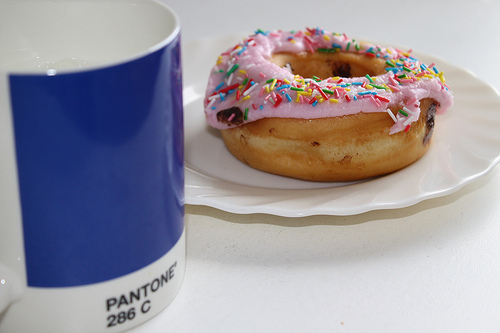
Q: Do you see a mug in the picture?
A: Yes, there is a mug.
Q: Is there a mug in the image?
A: Yes, there is a mug.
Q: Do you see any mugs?
A: Yes, there is a mug.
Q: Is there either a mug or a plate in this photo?
A: Yes, there is a mug.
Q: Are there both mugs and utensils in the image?
A: No, there is a mug but no utensils.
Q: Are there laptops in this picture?
A: No, there are no laptops.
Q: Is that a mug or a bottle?
A: That is a mug.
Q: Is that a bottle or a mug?
A: That is a mug.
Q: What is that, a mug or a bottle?
A: That is a mug.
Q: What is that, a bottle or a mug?
A: That is a mug.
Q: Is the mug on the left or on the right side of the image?
A: The mug is on the left of the image.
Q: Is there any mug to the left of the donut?
A: Yes, there is a mug to the left of the donut.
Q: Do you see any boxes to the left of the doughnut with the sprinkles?
A: No, there is a mug to the left of the donut.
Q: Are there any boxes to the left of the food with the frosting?
A: No, there is a mug to the left of the donut.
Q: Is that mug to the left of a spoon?
A: No, the mug is to the left of a donut.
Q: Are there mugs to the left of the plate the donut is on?
A: Yes, there is a mug to the left of the plate.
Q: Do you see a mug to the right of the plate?
A: No, the mug is to the left of the plate.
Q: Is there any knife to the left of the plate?
A: No, there is a mug to the left of the plate.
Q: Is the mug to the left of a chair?
A: No, the mug is to the left of the plate.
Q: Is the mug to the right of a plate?
A: No, the mug is to the left of a plate.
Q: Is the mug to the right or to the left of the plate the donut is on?
A: The mug is to the left of the plate.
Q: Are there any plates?
A: Yes, there is a plate.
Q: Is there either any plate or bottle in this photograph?
A: Yes, there is a plate.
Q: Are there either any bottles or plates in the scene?
A: Yes, there is a plate.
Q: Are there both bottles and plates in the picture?
A: No, there is a plate but no bottles.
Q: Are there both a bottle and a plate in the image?
A: No, there is a plate but no bottles.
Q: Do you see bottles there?
A: No, there are no bottles.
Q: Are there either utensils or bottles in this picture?
A: No, there are no bottles or utensils.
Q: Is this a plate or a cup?
A: This is a plate.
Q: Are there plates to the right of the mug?
A: Yes, there is a plate to the right of the mug.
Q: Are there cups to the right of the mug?
A: No, there is a plate to the right of the mug.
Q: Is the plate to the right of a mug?
A: Yes, the plate is to the right of a mug.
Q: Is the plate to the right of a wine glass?
A: No, the plate is to the right of a mug.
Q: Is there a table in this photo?
A: Yes, there is a table.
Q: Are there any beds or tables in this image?
A: Yes, there is a table.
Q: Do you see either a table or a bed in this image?
A: Yes, there is a table.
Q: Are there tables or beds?
A: Yes, there is a table.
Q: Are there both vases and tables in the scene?
A: No, there is a table but no vases.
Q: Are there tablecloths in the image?
A: No, there are no tablecloths.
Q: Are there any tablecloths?
A: No, there are no tablecloths.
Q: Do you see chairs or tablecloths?
A: No, there are no tablecloths or chairs.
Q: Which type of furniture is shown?
A: The furniture is a table.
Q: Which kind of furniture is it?
A: The piece of furniture is a table.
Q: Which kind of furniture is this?
A: This is a table.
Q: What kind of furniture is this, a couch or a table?
A: This is a table.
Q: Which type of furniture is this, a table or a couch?
A: This is a table.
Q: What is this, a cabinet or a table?
A: This is a table.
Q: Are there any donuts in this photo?
A: Yes, there is a donut.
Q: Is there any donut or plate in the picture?
A: Yes, there is a donut.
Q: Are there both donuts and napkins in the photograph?
A: No, there is a donut but no napkins.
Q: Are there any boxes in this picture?
A: No, there are no boxes.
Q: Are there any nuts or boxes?
A: No, there are no boxes or nuts.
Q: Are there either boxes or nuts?
A: No, there are no boxes or nuts.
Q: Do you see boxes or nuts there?
A: No, there are no boxes or nuts.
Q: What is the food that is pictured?
A: The food is a donut.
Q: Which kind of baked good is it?
A: The food is a donut.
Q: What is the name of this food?
A: This is a donut.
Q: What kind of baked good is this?
A: This is a donut.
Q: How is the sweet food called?
A: The food is a donut.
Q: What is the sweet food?
A: The food is a donut.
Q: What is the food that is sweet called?
A: The food is a donut.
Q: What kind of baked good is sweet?
A: The baked good is a donut.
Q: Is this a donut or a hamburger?
A: This is a donut.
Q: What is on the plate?
A: The doughnut is on the plate.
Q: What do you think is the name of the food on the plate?
A: The food is a donut.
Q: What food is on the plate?
A: The food is a donut.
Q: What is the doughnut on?
A: The doughnut is on the plate.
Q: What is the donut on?
A: The doughnut is on the plate.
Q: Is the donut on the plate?
A: Yes, the donut is on the plate.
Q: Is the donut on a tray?
A: No, the donut is on the plate.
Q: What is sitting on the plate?
A: The donut is sitting on the plate.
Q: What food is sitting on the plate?
A: The food is a donut.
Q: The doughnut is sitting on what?
A: The doughnut is sitting on the plate.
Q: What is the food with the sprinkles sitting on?
A: The doughnut is sitting on the plate.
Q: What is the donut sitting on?
A: The doughnut is sitting on the plate.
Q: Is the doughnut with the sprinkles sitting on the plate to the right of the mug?
A: Yes, the donut is sitting on the plate.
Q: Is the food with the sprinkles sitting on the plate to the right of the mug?
A: Yes, the donut is sitting on the plate.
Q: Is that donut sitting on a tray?
A: No, the donut is sitting on the plate.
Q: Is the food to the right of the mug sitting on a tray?
A: No, the donut is sitting on the plate.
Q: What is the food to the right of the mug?
A: The food is a donut.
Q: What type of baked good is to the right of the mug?
A: The food is a donut.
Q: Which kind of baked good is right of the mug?
A: The food is a donut.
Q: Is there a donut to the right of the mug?
A: Yes, there is a donut to the right of the mug.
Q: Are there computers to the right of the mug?
A: No, there is a donut to the right of the mug.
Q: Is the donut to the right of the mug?
A: Yes, the donut is to the right of the mug.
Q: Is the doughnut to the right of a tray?
A: No, the doughnut is to the right of the mug.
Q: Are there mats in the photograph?
A: No, there are no mats.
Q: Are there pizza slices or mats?
A: No, there are no mats or pizza slices.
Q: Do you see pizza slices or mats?
A: No, there are no mats or pizza slices.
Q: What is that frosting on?
A: The frosting is on the donut.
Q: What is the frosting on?
A: The frosting is on the donut.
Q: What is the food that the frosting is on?
A: The food is a donut.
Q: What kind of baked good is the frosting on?
A: The frosting is on the doughnut.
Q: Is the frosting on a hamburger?
A: No, the frosting is on a donut.